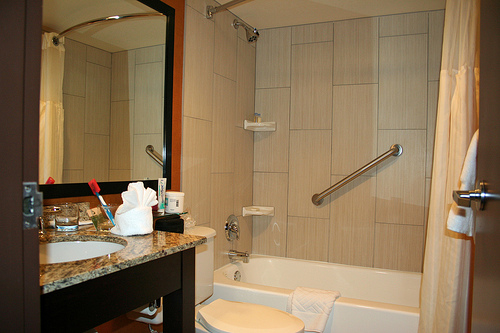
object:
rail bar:
[310, 142, 404, 207]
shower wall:
[251, 11, 446, 276]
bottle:
[253, 111, 261, 123]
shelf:
[241, 120, 276, 133]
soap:
[250, 208, 260, 211]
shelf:
[241, 204, 275, 218]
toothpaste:
[155, 177, 167, 215]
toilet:
[126, 223, 305, 332]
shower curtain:
[38, 26, 64, 185]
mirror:
[38, 0, 166, 184]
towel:
[285, 287, 339, 332]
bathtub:
[198, 252, 421, 332]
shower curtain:
[416, 0, 478, 333]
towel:
[445, 125, 478, 237]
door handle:
[449, 177, 486, 209]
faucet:
[229, 249, 252, 263]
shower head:
[231, 17, 260, 43]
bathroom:
[0, 3, 500, 333]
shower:
[179, 0, 445, 333]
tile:
[373, 30, 428, 131]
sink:
[40, 231, 127, 267]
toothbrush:
[86, 178, 115, 222]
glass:
[96, 202, 120, 229]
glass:
[53, 198, 80, 231]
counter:
[37, 215, 205, 333]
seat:
[199, 297, 303, 332]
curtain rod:
[53, 9, 164, 44]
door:
[456, 0, 497, 332]